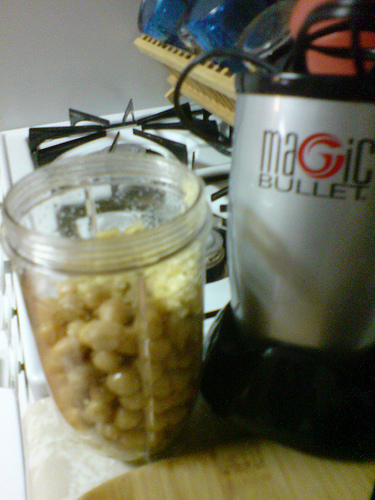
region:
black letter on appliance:
[259, 129, 282, 175]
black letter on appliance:
[283, 130, 297, 176]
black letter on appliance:
[342, 135, 354, 183]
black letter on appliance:
[353, 136, 371, 184]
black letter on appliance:
[256, 172, 271, 189]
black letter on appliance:
[274, 174, 294, 195]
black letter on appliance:
[292, 174, 308, 197]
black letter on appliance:
[311, 179, 328, 200]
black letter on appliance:
[328, 179, 349, 202]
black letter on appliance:
[349, 183, 366, 199]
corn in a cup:
[17, 148, 204, 464]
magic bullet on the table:
[217, 103, 371, 229]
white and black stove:
[40, 95, 209, 165]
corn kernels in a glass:
[52, 290, 184, 434]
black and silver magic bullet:
[225, 86, 368, 370]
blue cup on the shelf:
[139, 0, 185, 51]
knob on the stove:
[4, 348, 28, 396]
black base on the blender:
[217, 301, 373, 438]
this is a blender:
[222, 100, 368, 389]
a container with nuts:
[18, 203, 195, 459]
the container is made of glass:
[1, 160, 220, 471]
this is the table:
[251, 465, 270, 489]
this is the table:
[179, 467, 216, 487]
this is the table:
[116, 481, 143, 497]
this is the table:
[95, 486, 117, 496]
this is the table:
[333, 460, 349, 494]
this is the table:
[209, 466, 326, 486]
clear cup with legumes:
[16, 184, 181, 448]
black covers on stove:
[62, 101, 251, 287]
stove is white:
[52, 108, 236, 336]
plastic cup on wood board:
[16, 162, 182, 459]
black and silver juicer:
[187, 89, 356, 377]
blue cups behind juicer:
[141, 1, 309, 92]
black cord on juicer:
[161, 38, 311, 154]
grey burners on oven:
[97, 136, 157, 168]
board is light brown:
[97, 441, 312, 486]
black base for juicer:
[196, 304, 362, 448]